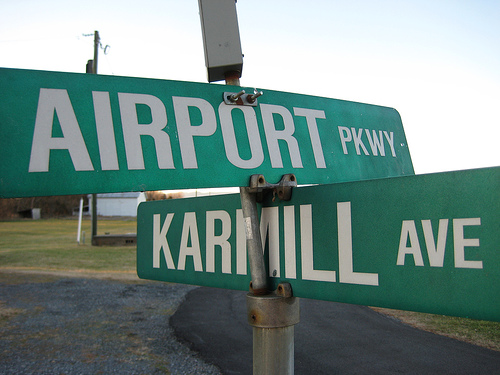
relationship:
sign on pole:
[0, 66, 413, 201] [230, 262, 297, 372]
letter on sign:
[92, 91, 119, 171] [0, 66, 413, 201]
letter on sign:
[87, 84, 129, 180] [102, 130, 494, 344]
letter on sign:
[225, 84, 271, 174] [2, 49, 485, 329]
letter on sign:
[118, 86, 176, 177] [2, 49, 485, 329]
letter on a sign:
[259, 101, 304, 169] [0, 66, 413, 201]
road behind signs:
[288, 302, 496, 371] [136, 165, 498, 316]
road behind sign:
[288, 302, 496, 371] [129, 180, 499, 327]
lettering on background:
[27, 86, 337, 181] [6, 69, 422, 193]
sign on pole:
[0, 66, 413, 201] [238, 280, 308, 372]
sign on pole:
[129, 180, 499, 327] [238, 280, 308, 372]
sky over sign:
[4, 5, 499, 198] [0, 66, 413, 201]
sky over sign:
[4, 5, 499, 198] [129, 180, 499, 327]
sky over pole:
[4, 5, 499, 198] [241, 292, 306, 373]